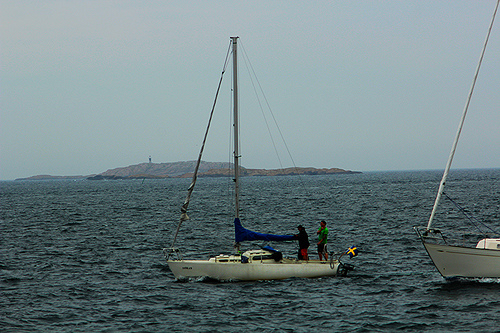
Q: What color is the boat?
A: White.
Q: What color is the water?
A: Gray.